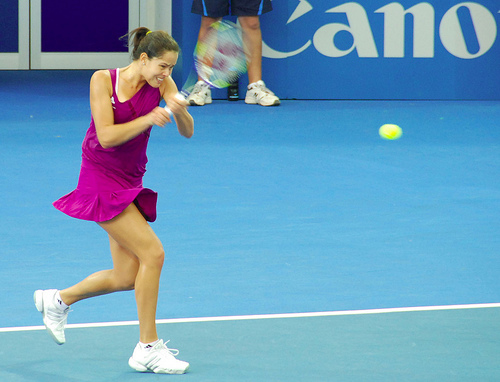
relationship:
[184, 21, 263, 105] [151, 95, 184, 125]
racquet in hands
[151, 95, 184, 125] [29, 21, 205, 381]
hands of woman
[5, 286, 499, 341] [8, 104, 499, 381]
line on court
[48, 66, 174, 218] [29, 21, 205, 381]
outfit of woman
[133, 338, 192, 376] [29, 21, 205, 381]
shoe on woman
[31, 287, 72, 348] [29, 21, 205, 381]
shoe on woman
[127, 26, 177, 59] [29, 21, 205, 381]
hair on woman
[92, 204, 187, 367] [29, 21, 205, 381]
leg on woman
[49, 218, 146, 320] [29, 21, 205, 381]
leg on woman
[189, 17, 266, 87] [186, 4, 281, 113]
legs of person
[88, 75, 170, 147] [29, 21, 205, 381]
arm of woman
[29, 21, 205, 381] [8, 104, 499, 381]
woman on court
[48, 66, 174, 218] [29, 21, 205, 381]
outfit on woman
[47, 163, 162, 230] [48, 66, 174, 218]
skirt of outfit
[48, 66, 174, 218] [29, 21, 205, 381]
outfit of player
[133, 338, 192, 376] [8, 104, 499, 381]
sneaker on court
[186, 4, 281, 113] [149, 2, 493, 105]
person against wall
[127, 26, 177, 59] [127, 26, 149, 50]
hair in ponytail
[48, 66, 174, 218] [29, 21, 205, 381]
dress of player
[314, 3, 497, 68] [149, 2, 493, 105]
letters on sign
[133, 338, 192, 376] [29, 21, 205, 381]
shoe of player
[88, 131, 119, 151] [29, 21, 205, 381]
elbow of player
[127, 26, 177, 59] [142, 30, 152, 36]
hair with band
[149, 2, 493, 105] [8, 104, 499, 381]
wall surrounding court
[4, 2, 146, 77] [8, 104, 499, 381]
doors to court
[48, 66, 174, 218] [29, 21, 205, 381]
dress on woman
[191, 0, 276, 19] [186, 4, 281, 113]
shorts on man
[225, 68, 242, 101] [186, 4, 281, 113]
bottle under person